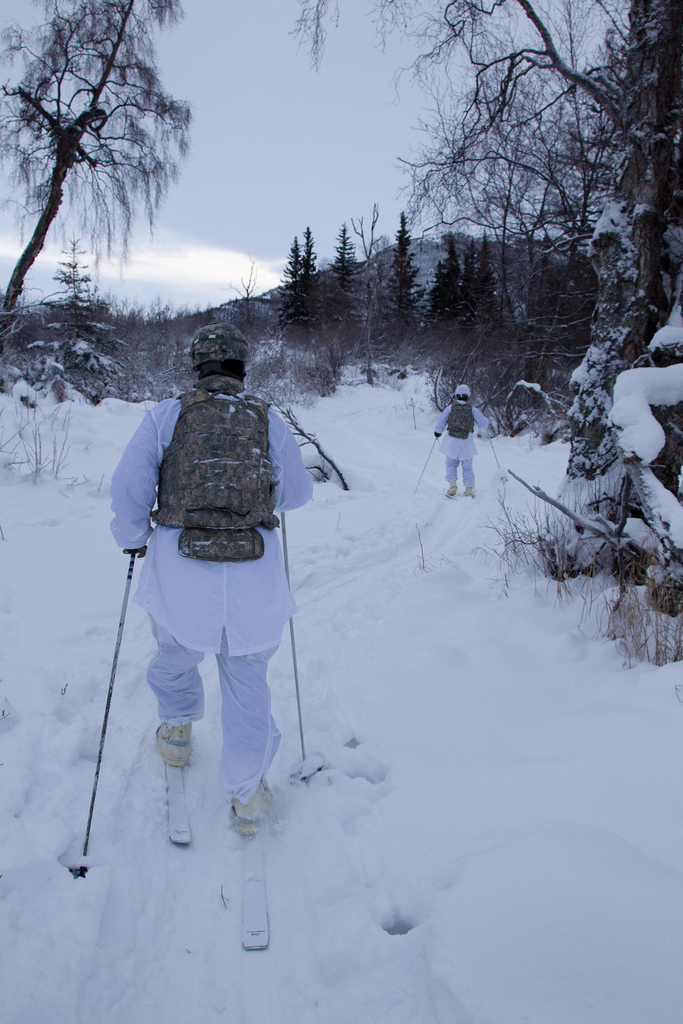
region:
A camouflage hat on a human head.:
[184, 311, 256, 377]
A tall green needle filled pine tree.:
[299, 221, 321, 333]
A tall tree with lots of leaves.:
[2, 0, 194, 338]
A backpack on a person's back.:
[146, 376, 275, 562]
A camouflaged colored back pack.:
[148, 387, 283, 566]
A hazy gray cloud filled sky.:
[0, 0, 631, 322]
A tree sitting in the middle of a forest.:
[40, 231, 128, 402]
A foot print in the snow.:
[381, 903, 416, 939]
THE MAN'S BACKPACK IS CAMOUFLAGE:
[143, 380, 307, 555]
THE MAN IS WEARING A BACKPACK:
[140, 382, 294, 575]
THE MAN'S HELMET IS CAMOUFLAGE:
[175, 310, 259, 382]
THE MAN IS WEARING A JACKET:
[104, 393, 344, 676]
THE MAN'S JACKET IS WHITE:
[99, 391, 326, 663]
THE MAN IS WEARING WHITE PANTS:
[124, 585, 280, 803]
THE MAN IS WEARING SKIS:
[144, 729, 279, 968]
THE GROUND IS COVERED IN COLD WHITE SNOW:
[0, 364, 680, 1021]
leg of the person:
[159, 674, 199, 750]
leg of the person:
[219, 678, 266, 747]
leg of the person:
[460, 461, 478, 485]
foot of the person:
[163, 715, 206, 770]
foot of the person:
[231, 785, 289, 848]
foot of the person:
[445, 476, 464, 493]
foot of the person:
[454, 476, 483, 506]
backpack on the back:
[194, 403, 256, 546]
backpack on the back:
[450, 396, 472, 442]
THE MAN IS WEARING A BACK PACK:
[144, 373, 298, 570]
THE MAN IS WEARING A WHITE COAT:
[97, 383, 334, 656]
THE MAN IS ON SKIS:
[106, 676, 290, 963]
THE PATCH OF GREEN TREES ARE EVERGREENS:
[251, 184, 504, 375]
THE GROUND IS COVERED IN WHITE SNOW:
[0, 328, 677, 1018]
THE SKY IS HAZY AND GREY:
[0, 2, 672, 332]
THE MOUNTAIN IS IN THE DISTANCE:
[209, 219, 639, 405]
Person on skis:
[153, 675, 291, 961]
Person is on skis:
[143, 678, 303, 965]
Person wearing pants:
[137, 572, 290, 806]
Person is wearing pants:
[138, 607, 299, 803]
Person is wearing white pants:
[143, 595, 291, 809]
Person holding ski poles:
[59, 488, 331, 887]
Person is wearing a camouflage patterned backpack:
[156, 378, 292, 572]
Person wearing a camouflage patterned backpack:
[135, 379, 300, 566]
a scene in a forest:
[49, 59, 666, 551]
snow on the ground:
[0, 360, 679, 1022]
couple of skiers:
[59, 296, 534, 935]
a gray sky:
[2, 4, 680, 314]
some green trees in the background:
[8, 185, 680, 459]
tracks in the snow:
[53, 350, 585, 678]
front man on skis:
[400, 371, 514, 503]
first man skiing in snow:
[420, 373, 496, 505]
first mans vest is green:
[441, 394, 482, 445]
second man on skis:
[115, 317, 330, 853]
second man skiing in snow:
[104, 317, 322, 861]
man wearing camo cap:
[181, 310, 250, 373]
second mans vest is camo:
[146, 371, 285, 569]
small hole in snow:
[372, 897, 418, 943]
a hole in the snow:
[376, 904, 422, 945]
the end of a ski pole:
[59, 852, 101, 893]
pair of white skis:
[149, 750, 267, 967]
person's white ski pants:
[135, 623, 295, 808]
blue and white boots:
[153, 703, 284, 841]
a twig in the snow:
[411, 509, 434, 572]